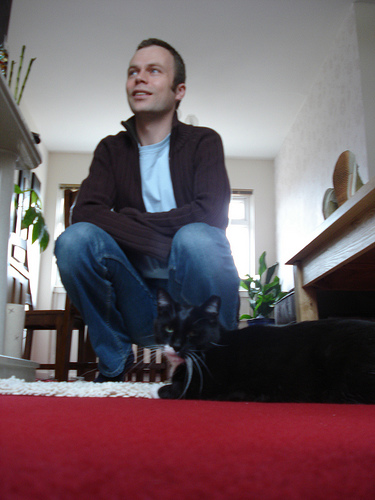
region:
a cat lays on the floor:
[139, 272, 374, 416]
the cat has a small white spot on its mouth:
[164, 341, 176, 356]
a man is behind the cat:
[44, 17, 243, 376]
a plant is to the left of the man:
[13, 182, 51, 349]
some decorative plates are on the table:
[308, 145, 363, 222]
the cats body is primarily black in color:
[153, 283, 373, 423]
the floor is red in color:
[2, 397, 371, 499]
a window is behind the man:
[53, 174, 260, 287]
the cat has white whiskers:
[114, 337, 209, 403]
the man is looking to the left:
[121, 25, 195, 132]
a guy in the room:
[49, 36, 248, 387]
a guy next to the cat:
[51, 34, 369, 407]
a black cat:
[145, 282, 373, 405]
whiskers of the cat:
[175, 350, 212, 404]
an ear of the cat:
[197, 292, 223, 320]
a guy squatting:
[50, 35, 245, 384]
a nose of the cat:
[171, 332, 185, 350]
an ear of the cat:
[152, 283, 176, 308]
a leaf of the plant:
[256, 248, 268, 278]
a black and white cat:
[128, 280, 373, 398]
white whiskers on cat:
[105, 340, 263, 397]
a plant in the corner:
[237, 251, 286, 345]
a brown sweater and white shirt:
[35, 107, 239, 281]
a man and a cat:
[63, 33, 373, 415]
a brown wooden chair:
[3, 241, 80, 385]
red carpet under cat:
[11, 362, 367, 499]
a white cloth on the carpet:
[8, 370, 229, 419]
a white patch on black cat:
[160, 340, 184, 371]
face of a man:
[125, 38, 186, 126]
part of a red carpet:
[136, 423, 201, 472]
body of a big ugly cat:
[268, 355, 321, 382]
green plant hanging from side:
[15, 168, 47, 249]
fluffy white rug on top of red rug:
[0, 372, 172, 402]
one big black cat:
[150, 286, 373, 409]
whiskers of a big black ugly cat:
[116, 342, 204, 390]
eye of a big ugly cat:
[159, 317, 175, 336]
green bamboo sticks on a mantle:
[6, 38, 49, 104]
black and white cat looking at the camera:
[150, 286, 371, 401]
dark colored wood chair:
[24, 275, 74, 377]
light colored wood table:
[285, 180, 372, 324]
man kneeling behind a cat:
[52, 39, 252, 396]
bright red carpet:
[0, 394, 374, 496]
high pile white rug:
[0, 376, 170, 396]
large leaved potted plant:
[237, 253, 283, 325]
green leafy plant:
[9, 184, 50, 249]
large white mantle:
[0, 71, 41, 378]